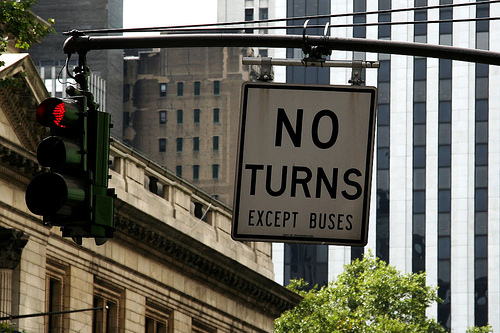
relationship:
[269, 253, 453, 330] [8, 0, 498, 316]
tree in front of building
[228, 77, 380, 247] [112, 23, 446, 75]
sign hanging  from pole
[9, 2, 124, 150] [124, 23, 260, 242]
building next to building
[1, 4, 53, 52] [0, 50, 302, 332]
tree near building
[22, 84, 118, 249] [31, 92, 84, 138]
stoplight displays light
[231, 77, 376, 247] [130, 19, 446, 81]
sign on pole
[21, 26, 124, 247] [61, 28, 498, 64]
stoplight attached to pole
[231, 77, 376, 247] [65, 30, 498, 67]
sign hanging from pole